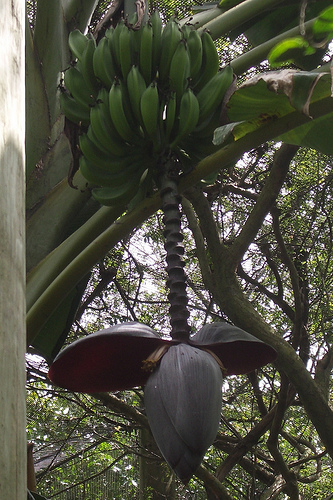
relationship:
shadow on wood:
[190, 180, 240, 275] [185, 181, 333, 451]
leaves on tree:
[216, 1, 331, 163] [9, 7, 331, 494]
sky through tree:
[86, 200, 224, 340] [9, 7, 331, 494]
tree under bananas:
[9, 7, 331, 494] [58, 10, 244, 202]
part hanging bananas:
[59, 164, 304, 469] [58, 10, 244, 202]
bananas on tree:
[58, 10, 244, 202] [9, 7, 331, 494]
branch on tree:
[170, 164, 326, 353] [9, 7, 331, 494]